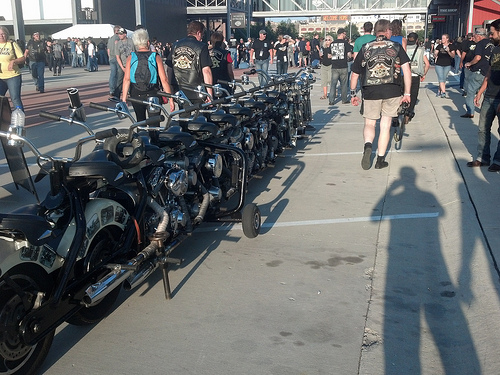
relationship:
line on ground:
[367, 238, 383, 323] [233, 49, 496, 338]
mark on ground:
[309, 252, 364, 271] [4, 66, 498, 370]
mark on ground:
[264, 256, 282, 268] [4, 66, 498, 370]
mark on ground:
[327, 182, 334, 188] [4, 66, 498, 370]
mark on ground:
[438, 289, 455, 301] [4, 66, 498, 370]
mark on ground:
[279, 330, 291, 338] [4, 66, 498, 370]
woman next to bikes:
[119, 29, 176, 127] [0, 60, 322, 373]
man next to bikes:
[166, 20, 214, 119] [0, 60, 322, 373]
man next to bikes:
[204, 32, 235, 98] [0, 60, 322, 373]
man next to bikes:
[350, 20, 413, 169] [0, 60, 322, 373]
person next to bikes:
[390, 17, 404, 44] [0, 60, 322, 373]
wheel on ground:
[236, 188, 287, 258] [4, 66, 498, 370]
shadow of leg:
[369, 165, 465, 374] [376, 290, 427, 368]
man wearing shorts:
[350, 20, 413, 169] [361, 93, 405, 120]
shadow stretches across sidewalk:
[369, 165, 481, 374] [37, 67, 499, 374]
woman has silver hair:
[119, 29, 176, 127] [130, 28, 150, 47]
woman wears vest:
[119, 29, 176, 127] [125, 51, 161, 88]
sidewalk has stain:
[322, 116, 468, 367] [440, 290, 455, 298]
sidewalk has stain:
[322, 116, 468, 367] [344, 255, 363, 264]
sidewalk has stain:
[322, 116, 468, 367] [264, 257, 281, 268]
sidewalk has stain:
[322, 116, 468, 367] [325, 182, 337, 187]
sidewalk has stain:
[322, 116, 468, 367] [280, 330, 294, 338]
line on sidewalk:
[218, 205, 443, 234] [423, 44, 499, 331]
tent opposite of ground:
[44, 22, 137, 42] [4, 66, 498, 370]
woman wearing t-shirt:
[0, 27, 25, 116] [1, 41, 21, 78]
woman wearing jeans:
[0, 27, 25, 116] [0, 72, 27, 111]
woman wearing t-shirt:
[105, 22, 167, 122] [433, 40, 453, 65]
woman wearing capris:
[105, 22, 167, 122] [434, 60, 453, 80]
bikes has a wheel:
[0, 60, 320, 375] [0, 260, 61, 373]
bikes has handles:
[0, 60, 320, 375] [0, 126, 120, 163]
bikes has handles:
[0, 60, 320, 375] [35, 108, 167, 148]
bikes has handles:
[0, 60, 320, 375] [77, 77, 227, 132]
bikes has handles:
[0, 60, 320, 375] [197, 95, 233, 108]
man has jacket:
[168, 20, 213, 103] [165, 35, 213, 99]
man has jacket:
[166, 20, 214, 119] [168, 34, 204, 86]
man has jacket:
[166, 20, 214, 119] [169, 40, 202, 89]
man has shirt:
[353, 24, 415, 109] [349, 37, 409, 102]